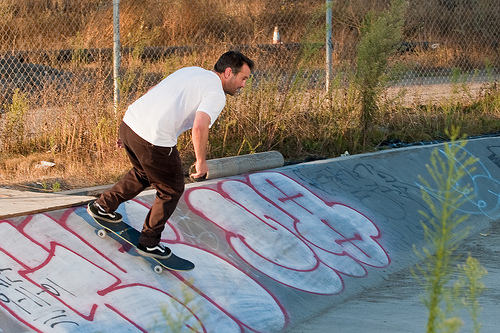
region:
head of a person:
[203, 52, 270, 92]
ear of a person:
[219, 54, 239, 75]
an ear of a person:
[217, 67, 237, 81]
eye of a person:
[235, 68, 259, 80]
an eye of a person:
[235, 74, 250, 84]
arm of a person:
[183, 105, 228, 163]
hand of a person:
[180, 161, 222, 188]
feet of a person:
[130, 236, 187, 271]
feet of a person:
[79, 202, 122, 229]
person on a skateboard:
[66, 45, 311, 273]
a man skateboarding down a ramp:
[51, 16, 266, 290]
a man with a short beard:
[208, 35, 259, 108]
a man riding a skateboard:
[49, 28, 271, 280]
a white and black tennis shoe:
[133, 230, 173, 263]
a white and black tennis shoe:
[78, 194, 128, 226]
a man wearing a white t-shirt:
[118, 30, 263, 147]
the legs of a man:
[81, 128, 191, 251]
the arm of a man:
[178, 100, 228, 191]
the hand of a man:
[188, 158, 208, 183]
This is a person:
[87, 36, 268, 277]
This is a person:
[68, 38, 310, 310]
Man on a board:
[89, 197, 200, 282]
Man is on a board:
[83, 196, 200, 276]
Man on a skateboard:
[86, 198, 201, 283]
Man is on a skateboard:
[82, 194, 201, 281]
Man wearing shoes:
[86, 198, 176, 267]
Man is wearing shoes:
[87, 192, 174, 259]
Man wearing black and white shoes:
[81, 199, 176, 262]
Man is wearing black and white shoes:
[87, 195, 176, 261]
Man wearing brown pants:
[91, 110, 187, 245]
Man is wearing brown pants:
[100, 106, 187, 244]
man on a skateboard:
[135, 32, 277, 282]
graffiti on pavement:
[27, 207, 441, 305]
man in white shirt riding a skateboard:
[109, 33, 264, 280]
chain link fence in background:
[68, 10, 472, 95]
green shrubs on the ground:
[305, 13, 460, 126]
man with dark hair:
[214, 44, 255, 105]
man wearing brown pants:
[115, 15, 249, 245]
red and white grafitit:
[197, 178, 359, 314]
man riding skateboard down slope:
[58, 2, 355, 264]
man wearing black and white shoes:
[116, 23, 273, 282]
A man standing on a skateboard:
[87, 48, 254, 273]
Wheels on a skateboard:
[152, 263, 163, 275]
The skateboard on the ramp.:
[82, 205, 204, 289]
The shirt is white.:
[128, 71, 215, 136]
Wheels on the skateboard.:
[93, 227, 108, 238]